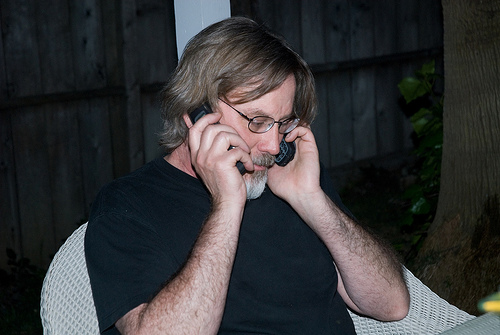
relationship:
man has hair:
[84, 16, 408, 335] [146, 13, 323, 153]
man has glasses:
[84, 16, 408, 335] [222, 90, 314, 142]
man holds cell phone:
[84, 16, 408, 335] [274, 137, 295, 167]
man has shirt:
[84, 16, 408, 335] [73, 140, 363, 333]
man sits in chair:
[84, 16, 408, 335] [30, 190, 474, 331]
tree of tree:
[419, 4, 500, 283] [405, 8, 484, 318]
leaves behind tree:
[397, 58, 433, 178] [432, 4, 482, 271]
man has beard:
[84, 16, 408, 335] [232, 143, 282, 205]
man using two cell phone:
[84, 16, 408, 335] [274, 137, 295, 167]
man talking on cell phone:
[84, 16, 408, 335] [274, 137, 295, 167]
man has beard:
[84, 16, 408, 335] [243, 153, 277, 200]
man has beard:
[84, 16, 408, 335] [227, 162, 271, 199]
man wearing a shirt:
[84, 16, 408, 335] [84, 154, 355, 335]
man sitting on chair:
[84, 16, 408, 335] [30, 190, 474, 331]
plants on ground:
[324, 49, 449, 260] [387, 215, 474, 292]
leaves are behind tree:
[397, 58, 442, 178] [419, 4, 500, 283]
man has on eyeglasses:
[84, 16, 408, 335] [244, 112, 300, 135]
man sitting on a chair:
[84, 16, 408, 335] [46, 273, 76, 317]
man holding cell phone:
[84, 16, 408, 335] [186, 102, 206, 116]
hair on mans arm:
[385, 249, 395, 265] [315, 193, 405, 317]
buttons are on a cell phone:
[280, 149, 290, 156] [281, 143, 296, 159]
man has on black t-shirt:
[138, 18, 373, 308] [262, 254, 325, 317]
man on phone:
[84, 16, 408, 335] [276, 142, 295, 160]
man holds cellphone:
[84, 16, 408, 335] [277, 136, 294, 168]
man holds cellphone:
[84, 16, 408, 335] [276, 129, 299, 163]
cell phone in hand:
[187, 106, 208, 124] [182, 111, 254, 201]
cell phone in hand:
[274, 137, 295, 167] [267, 130, 325, 204]